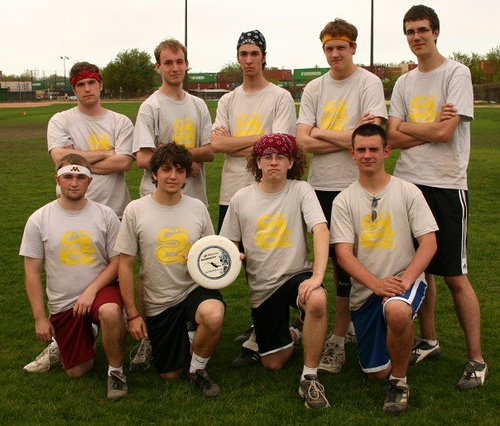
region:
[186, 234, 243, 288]
White frisbee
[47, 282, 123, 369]
Red shorts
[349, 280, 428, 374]
Blue shorts with white strips on sides and trim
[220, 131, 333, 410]
Man wearing bandana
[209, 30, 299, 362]
Man wearing bandana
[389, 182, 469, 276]
Black shorts with white stripes along sides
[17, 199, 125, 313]
White t-shirt with yellow logo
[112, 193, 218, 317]
White t-shirt with yellow logo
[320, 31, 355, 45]
Orange bandana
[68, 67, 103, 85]
Red bandana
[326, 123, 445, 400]
player on the field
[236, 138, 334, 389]
player on the field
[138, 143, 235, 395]
player on the field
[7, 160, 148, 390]
player on the field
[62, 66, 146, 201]
player on the field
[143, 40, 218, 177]
player on the field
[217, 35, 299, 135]
player on the field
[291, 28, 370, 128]
player on the field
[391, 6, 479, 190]
player on the field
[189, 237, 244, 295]
frisbee in player's hand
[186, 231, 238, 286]
a white Frisbee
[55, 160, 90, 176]
a white headband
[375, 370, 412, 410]
the shoe of a man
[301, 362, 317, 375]
a boy's white sock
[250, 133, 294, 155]
a red and white bandanna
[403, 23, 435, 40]
a boy's eyeglasses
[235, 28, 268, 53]
a black and white bandanna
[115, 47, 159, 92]
a large green tree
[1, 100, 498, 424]
a large green field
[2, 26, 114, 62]
part of a white sky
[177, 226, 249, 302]
white frisbee held by two people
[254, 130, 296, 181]
person wearing a red bandana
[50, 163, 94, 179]
person wearing a white headband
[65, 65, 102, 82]
person wearing a red headband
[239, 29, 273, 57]
person wearing a blue bandana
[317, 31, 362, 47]
person wearing a yellow headband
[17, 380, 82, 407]
green grass on the field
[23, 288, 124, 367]
person wearing burgundy shorts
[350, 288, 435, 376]
person wearing blue shorts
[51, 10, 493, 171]
five boys with arms folded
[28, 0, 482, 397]
a group of young men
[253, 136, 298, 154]
a red scarf on head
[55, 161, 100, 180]
a white sweat band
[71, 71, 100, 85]
a red sweat band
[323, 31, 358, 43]
a yellow sweat band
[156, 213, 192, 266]
a yellow snake on a shirt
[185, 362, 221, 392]
a gray tennis shoe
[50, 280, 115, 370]
a red pair of shorts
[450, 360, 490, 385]
a gray and white shoe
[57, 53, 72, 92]
a metal light pole